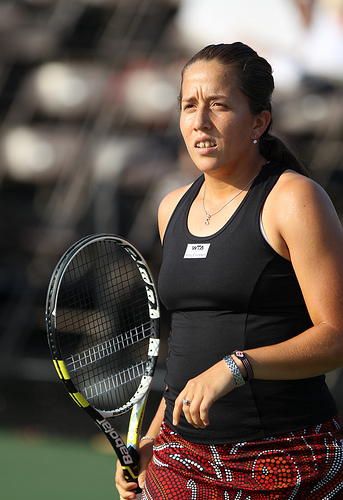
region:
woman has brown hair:
[179, 53, 286, 120]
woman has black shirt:
[157, 185, 319, 435]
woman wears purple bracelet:
[224, 349, 262, 399]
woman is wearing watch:
[210, 332, 257, 395]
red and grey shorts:
[154, 422, 338, 492]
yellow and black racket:
[46, 221, 179, 444]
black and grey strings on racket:
[59, 271, 153, 407]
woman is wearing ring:
[175, 393, 199, 422]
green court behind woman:
[25, 447, 113, 471]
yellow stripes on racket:
[55, 337, 129, 467]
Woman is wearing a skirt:
[126, 412, 340, 499]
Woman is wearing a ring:
[180, 394, 194, 408]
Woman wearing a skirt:
[141, 416, 341, 498]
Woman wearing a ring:
[177, 394, 196, 407]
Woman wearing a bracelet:
[218, 352, 242, 385]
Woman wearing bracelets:
[219, 345, 256, 386]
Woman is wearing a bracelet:
[221, 353, 246, 386]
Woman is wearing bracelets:
[220, 348, 258, 389]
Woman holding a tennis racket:
[40, 230, 163, 495]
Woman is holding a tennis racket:
[44, 228, 161, 495]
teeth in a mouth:
[195, 141, 215, 147]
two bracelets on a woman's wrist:
[222, 351, 260, 386]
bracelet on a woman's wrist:
[220, 355, 243, 385]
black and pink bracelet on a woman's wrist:
[235, 348, 257, 378]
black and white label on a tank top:
[181, 244, 213, 259]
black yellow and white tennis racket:
[40, 229, 162, 498]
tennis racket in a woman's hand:
[41, 231, 163, 499]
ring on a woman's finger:
[182, 400, 191, 407]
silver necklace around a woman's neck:
[196, 180, 257, 228]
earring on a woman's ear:
[252, 137, 259, 144]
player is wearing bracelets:
[209, 343, 259, 407]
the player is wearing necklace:
[190, 179, 253, 254]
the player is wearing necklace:
[187, 184, 231, 227]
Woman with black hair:
[169, 34, 285, 186]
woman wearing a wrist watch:
[219, 347, 259, 398]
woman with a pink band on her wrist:
[232, 341, 262, 383]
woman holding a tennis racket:
[109, 432, 156, 499]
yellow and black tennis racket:
[53, 334, 168, 475]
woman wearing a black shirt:
[146, 194, 308, 430]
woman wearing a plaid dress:
[149, 414, 331, 498]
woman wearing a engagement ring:
[177, 392, 194, 413]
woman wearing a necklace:
[190, 179, 251, 228]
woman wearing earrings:
[252, 134, 259, 145]